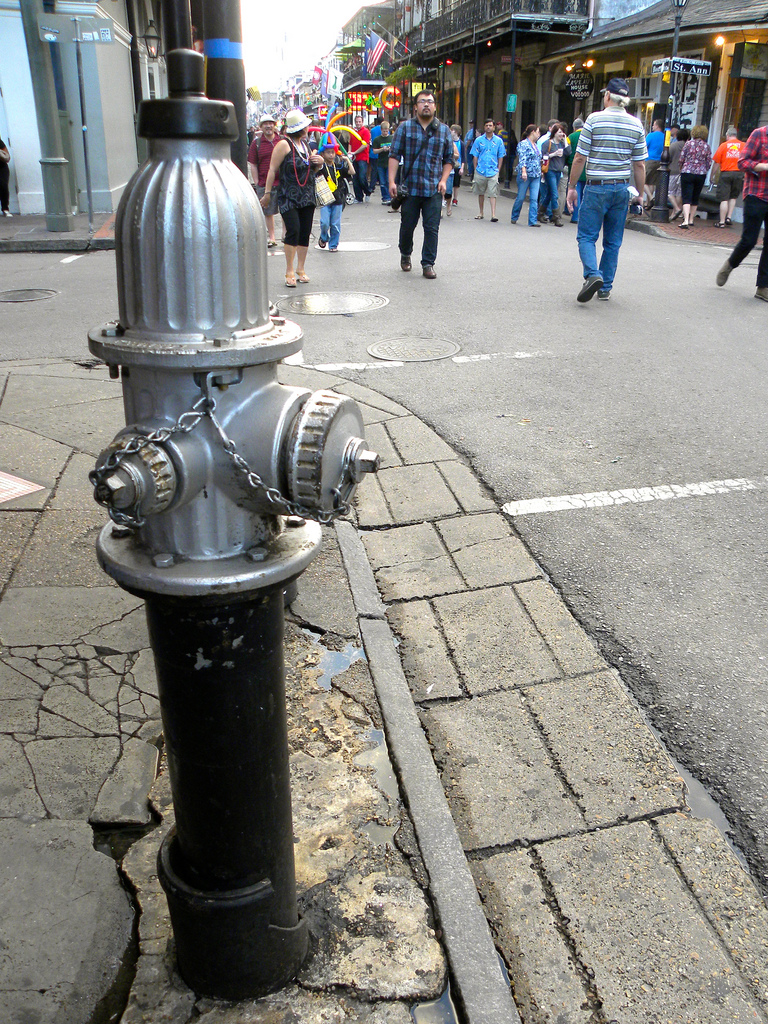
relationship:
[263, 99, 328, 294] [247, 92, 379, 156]
person in hat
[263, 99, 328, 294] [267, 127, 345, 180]
person with necklace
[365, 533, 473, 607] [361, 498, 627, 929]
tile in floor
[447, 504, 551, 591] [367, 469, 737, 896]
tile in floor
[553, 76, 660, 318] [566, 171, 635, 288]
man wearing blue jeans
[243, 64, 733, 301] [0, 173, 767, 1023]
people walking on floor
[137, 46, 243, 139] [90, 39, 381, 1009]
tip of hydrant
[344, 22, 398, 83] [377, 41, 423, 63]
flag hanging from pole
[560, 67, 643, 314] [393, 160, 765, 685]
person walking on road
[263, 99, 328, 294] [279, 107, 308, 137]
person wearing hat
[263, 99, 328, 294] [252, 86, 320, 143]
person wearing a hat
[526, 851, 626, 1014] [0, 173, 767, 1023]
lines in floor